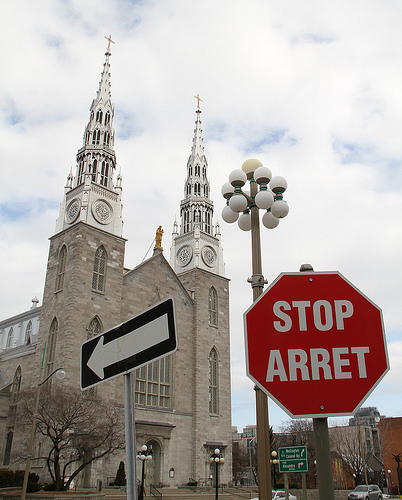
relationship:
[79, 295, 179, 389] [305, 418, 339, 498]
sign on pole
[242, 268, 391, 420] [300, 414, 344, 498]
red sign on pole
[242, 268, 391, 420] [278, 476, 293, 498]
red sign on pole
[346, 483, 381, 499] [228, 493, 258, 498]
car on curb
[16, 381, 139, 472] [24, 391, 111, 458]
tree with leaves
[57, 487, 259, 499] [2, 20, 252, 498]
steps front church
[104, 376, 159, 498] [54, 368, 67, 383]
pole has lamp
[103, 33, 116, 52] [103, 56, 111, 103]
cross on steeple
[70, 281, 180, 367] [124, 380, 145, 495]
sign on pole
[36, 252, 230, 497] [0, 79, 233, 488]
building of church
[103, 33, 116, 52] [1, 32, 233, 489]
cross on building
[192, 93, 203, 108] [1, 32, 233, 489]
cross on building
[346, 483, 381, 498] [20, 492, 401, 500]
car on road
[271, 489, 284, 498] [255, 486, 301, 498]
car on street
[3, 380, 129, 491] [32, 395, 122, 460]
tree no leaves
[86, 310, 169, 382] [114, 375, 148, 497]
arrow on pole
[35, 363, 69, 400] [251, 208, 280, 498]
lamp on pole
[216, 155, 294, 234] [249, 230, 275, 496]
lights on pole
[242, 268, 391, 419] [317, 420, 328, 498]
red sign on pole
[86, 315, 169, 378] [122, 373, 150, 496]
arrow on pole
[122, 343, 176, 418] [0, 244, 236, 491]
window on building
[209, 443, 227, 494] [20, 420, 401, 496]
pole on road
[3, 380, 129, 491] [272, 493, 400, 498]
tree on road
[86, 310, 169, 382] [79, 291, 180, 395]
arrow on sign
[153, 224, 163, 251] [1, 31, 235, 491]
statue on church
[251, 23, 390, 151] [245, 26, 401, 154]
clouds in sky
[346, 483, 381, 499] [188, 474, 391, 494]
car in street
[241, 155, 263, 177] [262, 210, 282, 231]
lights has light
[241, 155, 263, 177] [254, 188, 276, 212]
lights has light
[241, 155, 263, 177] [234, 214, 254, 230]
lights has light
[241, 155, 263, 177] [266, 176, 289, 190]
lights has light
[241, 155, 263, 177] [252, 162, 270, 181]
lights has light